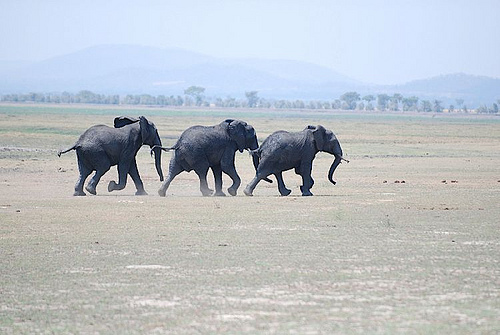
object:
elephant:
[57, 114, 163, 196]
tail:
[56, 146, 77, 154]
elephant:
[151, 120, 272, 198]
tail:
[151, 145, 177, 154]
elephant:
[244, 125, 350, 196]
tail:
[247, 148, 262, 154]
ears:
[140, 115, 150, 143]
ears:
[224, 119, 246, 153]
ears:
[313, 124, 326, 152]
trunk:
[153, 136, 164, 183]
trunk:
[250, 141, 272, 183]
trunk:
[328, 152, 340, 185]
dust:
[67, 182, 313, 199]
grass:
[1, 103, 499, 333]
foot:
[108, 179, 117, 192]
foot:
[135, 190, 148, 197]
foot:
[86, 185, 97, 195]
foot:
[73, 187, 85, 196]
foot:
[158, 185, 166, 196]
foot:
[200, 187, 212, 195]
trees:
[430, 97, 445, 112]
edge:
[2, 103, 499, 113]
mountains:
[1, 48, 498, 102]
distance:
[1, 1, 499, 129]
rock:
[16, 209, 21, 211]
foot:
[214, 189, 226, 197]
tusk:
[337, 153, 350, 163]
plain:
[0, 103, 499, 334]